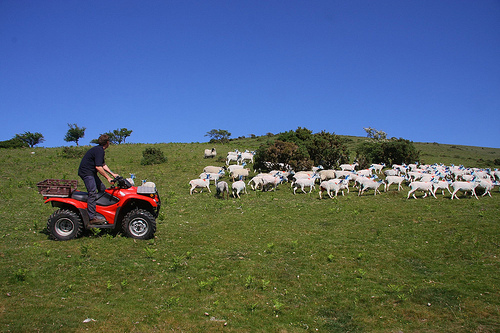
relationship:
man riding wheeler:
[77, 132, 121, 224] [39, 173, 161, 239]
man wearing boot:
[77, 132, 121, 224] [90, 214, 107, 227]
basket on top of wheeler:
[37, 178, 78, 197] [39, 173, 161, 239]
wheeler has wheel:
[39, 173, 161, 239] [47, 209, 85, 239]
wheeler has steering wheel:
[39, 173, 161, 239] [110, 174, 123, 183]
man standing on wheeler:
[77, 132, 121, 224] [39, 173, 161, 239]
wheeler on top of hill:
[39, 173, 161, 239] [3, 132, 499, 331]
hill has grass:
[3, 132, 499, 331] [0, 135, 498, 330]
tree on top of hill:
[62, 122, 85, 148] [3, 132, 499, 331]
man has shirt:
[77, 132, 121, 224] [78, 144, 105, 178]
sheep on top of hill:
[318, 178, 348, 199] [3, 132, 499, 331]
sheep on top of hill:
[205, 146, 216, 159] [3, 132, 499, 331]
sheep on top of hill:
[449, 178, 481, 201] [3, 132, 499, 331]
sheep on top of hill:
[257, 173, 288, 192] [3, 132, 499, 331]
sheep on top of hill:
[189, 177, 212, 196] [3, 132, 499, 331]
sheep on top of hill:
[358, 177, 385, 198] [3, 132, 499, 331]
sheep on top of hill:
[407, 179, 439, 202] [3, 132, 499, 331]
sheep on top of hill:
[293, 176, 319, 195] [3, 132, 499, 331]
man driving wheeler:
[77, 132, 121, 224] [39, 173, 161, 239]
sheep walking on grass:
[189, 177, 212, 196] [0, 135, 498, 330]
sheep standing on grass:
[407, 179, 439, 202] [0, 135, 498, 330]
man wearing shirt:
[77, 132, 121, 224] [78, 144, 105, 178]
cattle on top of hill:
[189, 146, 500, 201] [3, 132, 499, 331]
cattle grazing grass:
[189, 146, 500, 201] [0, 135, 498, 330]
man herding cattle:
[77, 132, 121, 224] [189, 146, 500, 201]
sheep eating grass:
[257, 173, 288, 192] [0, 135, 498, 330]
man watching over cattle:
[77, 132, 121, 224] [189, 146, 500, 201]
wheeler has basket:
[39, 173, 161, 239] [37, 178, 78, 197]